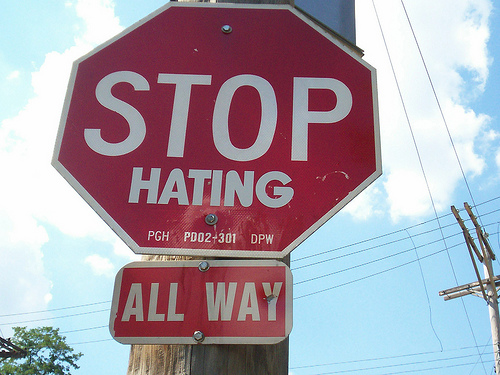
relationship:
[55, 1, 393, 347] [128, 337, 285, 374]
sign on pole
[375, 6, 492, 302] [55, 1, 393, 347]
lines above sign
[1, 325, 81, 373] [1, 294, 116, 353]
tree under wires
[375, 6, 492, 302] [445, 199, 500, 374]
lines on post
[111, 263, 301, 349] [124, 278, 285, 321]
sign says all way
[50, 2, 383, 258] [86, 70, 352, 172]
sign says stop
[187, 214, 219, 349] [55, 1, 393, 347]
rivet on sign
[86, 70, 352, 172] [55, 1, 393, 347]
stop on sign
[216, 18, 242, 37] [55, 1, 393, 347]
bolt on sign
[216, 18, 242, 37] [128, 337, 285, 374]
bolt on pole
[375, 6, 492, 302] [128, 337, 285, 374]
lines along pole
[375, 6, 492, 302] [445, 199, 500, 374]
lines along post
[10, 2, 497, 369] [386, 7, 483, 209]
sky has clouds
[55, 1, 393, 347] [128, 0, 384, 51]
sign has border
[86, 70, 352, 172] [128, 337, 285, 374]
stop on pole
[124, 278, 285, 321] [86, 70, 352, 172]
all way under stop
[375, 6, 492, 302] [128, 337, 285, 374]
lines on pole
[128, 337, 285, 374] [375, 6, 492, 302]
pole holding lines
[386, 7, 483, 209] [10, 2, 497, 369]
clouds in sky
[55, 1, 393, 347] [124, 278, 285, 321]
sign has all way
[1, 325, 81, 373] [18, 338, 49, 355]
tree has leaves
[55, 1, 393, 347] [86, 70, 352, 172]
sign says stop hating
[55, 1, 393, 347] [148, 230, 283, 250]
sign has number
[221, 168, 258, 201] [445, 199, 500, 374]
part of post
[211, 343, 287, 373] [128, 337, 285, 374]
part of pole